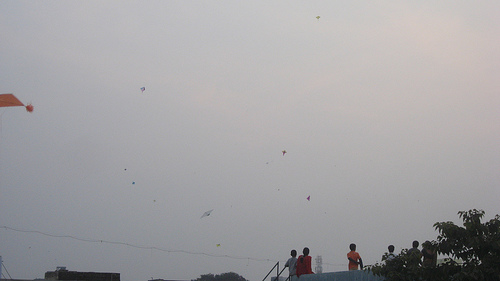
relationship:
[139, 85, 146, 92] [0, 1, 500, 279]
kite in sky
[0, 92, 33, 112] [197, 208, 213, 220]
kite in kite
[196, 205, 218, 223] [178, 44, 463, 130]
kite in sky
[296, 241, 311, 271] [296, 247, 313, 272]
woman wearing dress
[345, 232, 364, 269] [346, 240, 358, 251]
boy has head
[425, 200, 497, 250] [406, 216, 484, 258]
tree has leaves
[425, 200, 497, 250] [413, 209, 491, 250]
tree has branch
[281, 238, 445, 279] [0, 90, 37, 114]
people seeing kite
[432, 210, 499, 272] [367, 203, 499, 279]
leaves in tree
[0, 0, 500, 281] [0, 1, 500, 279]
cloud in sky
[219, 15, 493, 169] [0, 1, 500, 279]
clouds in sky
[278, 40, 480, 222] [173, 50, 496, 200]
clouds in sky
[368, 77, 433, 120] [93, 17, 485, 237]
white clouds in sky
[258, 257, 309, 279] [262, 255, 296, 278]
rails on stairs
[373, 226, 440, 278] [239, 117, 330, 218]
people flying kites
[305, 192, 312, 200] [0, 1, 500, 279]
kite in sky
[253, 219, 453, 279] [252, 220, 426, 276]
people in place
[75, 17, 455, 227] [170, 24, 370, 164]
cloud in sky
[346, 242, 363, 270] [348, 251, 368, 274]
boy in shirt